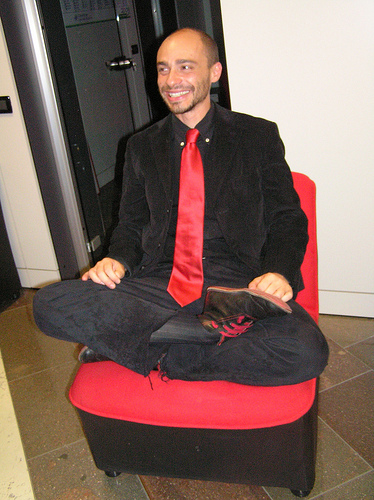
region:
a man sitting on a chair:
[34, 25, 353, 416]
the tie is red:
[144, 108, 219, 336]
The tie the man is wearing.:
[174, 132, 201, 306]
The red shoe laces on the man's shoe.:
[217, 313, 250, 338]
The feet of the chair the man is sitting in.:
[104, 470, 308, 497]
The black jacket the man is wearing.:
[111, 111, 304, 293]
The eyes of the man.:
[158, 63, 191, 71]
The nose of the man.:
[165, 79, 177, 88]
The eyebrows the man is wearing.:
[154, 59, 197, 66]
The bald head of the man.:
[157, 32, 202, 55]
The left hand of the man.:
[84, 257, 120, 286]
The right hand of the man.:
[244, 269, 289, 300]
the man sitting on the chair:
[67, 26, 329, 386]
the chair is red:
[75, 359, 303, 437]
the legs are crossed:
[46, 269, 289, 375]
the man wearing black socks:
[157, 309, 212, 348]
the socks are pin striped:
[152, 311, 215, 349]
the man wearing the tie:
[171, 125, 222, 300]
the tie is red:
[171, 128, 204, 308]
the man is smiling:
[147, 31, 230, 121]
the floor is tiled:
[9, 387, 86, 498]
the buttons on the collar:
[171, 138, 227, 151]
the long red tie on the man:
[165, 128, 205, 305]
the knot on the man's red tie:
[185, 128, 198, 142]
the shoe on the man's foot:
[197, 285, 292, 346]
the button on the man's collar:
[180, 142, 183, 145]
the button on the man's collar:
[204, 138, 209, 142]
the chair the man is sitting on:
[68, 172, 318, 497]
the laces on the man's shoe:
[209, 314, 252, 343]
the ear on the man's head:
[211, 62, 221, 82]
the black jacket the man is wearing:
[106, 100, 308, 301]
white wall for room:
[259, 22, 353, 116]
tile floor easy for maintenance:
[20, 362, 67, 441]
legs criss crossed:
[40, 268, 330, 376]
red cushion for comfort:
[69, 365, 307, 427]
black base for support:
[79, 410, 318, 483]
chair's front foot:
[289, 485, 311, 496]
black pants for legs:
[162, 343, 313, 375]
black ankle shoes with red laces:
[201, 285, 276, 328]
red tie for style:
[168, 125, 206, 305]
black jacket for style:
[216, 113, 298, 267]